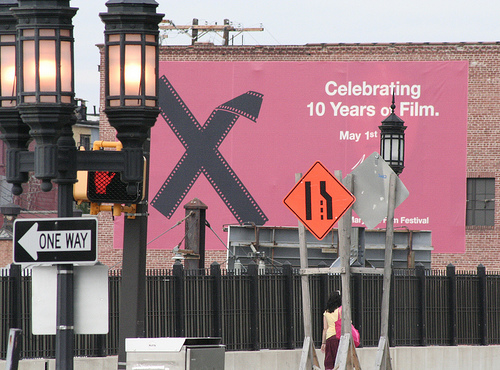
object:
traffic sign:
[12, 217, 99, 265]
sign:
[113, 59, 470, 252]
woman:
[321, 291, 360, 369]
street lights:
[96, 0, 165, 150]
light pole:
[54, 172, 75, 370]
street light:
[381, 88, 408, 177]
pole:
[116, 147, 147, 369]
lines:
[263, 25, 282, 46]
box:
[124, 335, 226, 369]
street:
[0, 369, 499, 370]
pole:
[294, 172, 313, 338]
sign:
[283, 159, 355, 240]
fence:
[389, 262, 499, 348]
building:
[96, 44, 500, 277]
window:
[463, 177, 496, 227]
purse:
[334, 305, 360, 348]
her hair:
[325, 289, 342, 314]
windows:
[80, 134, 91, 151]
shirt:
[322, 306, 353, 344]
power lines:
[239, 24, 260, 46]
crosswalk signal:
[87, 170, 140, 202]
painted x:
[148, 74, 268, 226]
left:
[17, 222, 91, 261]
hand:
[93, 170, 116, 195]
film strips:
[150, 73, 269, 226]